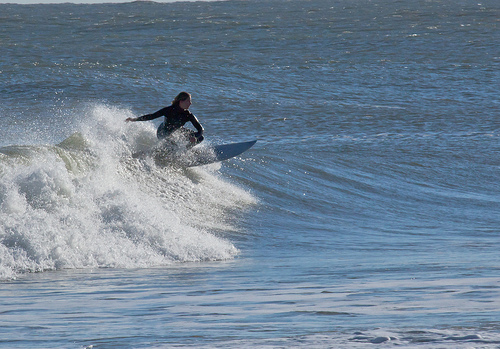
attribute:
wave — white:
[1, 99, 239, 347]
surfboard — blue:
[121, 126, 276, 195]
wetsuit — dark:
[162, 105, 182, 137]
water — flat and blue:
[22, 271, 498, 349]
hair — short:
[174, 75, 188, 109]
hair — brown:
[174, 99, 184, 103]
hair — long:
[158, 97, 181, 102]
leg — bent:
[177, 127, 207, 150]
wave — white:
[7, 146, 158, 246]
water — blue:
[336, 188, 456, 323]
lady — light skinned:
[125, 87, 207, 148]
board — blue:
[129, 137, 259, 168]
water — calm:
[320, 154, 446, 265]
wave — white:
[54, 136, 152, 226]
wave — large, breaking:
[6, 105, 240, 275]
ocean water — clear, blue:
[4, 4, 491, 344]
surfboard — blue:
[132, 136, 259, 168]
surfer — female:
[120, 91, 205, 149]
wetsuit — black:
[135, 107, 210, 134]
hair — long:
[166, 88, 190, 106]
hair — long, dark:
[167, 89, 188, 107]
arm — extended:
[129, 104, 164, 125]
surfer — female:
[124, 90, 207, 154]